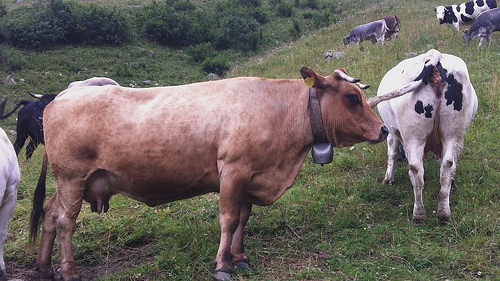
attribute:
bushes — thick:
[3, 0, 338, 70]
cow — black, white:
[382, 55, 469, 224]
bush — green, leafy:
[0, 0, 137, 50]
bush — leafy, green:
[132, 0, 209, 44]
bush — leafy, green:
[205, 0, 262, 50]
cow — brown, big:
[33, 68, 396, 277]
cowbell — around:
[312, 140, 334, 167]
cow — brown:
[24, 60, 395, 267]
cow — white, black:
[366, 47, 478, 224]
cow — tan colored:
[19, 51, 395, 280]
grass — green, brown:
[5, 4, 497, 279]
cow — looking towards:
[433, 0, 500, 32]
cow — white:
[360, 42, 484, 227]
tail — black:
[356, 38, 442, 107]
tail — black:
[0, 94, 27, 122]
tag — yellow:
[303, 75, 313, 88]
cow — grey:
[339, 20, 389, 56]